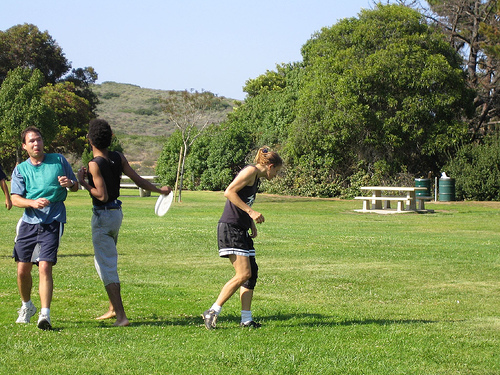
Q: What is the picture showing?
A: It is showing a field.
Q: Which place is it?
A: It is a field.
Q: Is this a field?
A: Yes, it is a field.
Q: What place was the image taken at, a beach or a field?
A: It was taken at a field.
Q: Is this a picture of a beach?
A: No, the picture is showing a field.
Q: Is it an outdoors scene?
A: Yes, it is outdoors.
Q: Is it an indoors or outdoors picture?
A: It is outdoors.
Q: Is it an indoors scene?
A: No, it is outdoors.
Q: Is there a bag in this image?
A: No, there are no bags.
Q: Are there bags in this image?
A: No, there are no bags.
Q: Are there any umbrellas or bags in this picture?
A: No, there are no bags or umbrellas.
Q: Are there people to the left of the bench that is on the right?
A: Yes, there are people to the left of the bench.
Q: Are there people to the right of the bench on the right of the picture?
A: No, the people are to the left of the bench.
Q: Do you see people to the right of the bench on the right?
A: No, the people are to the left of the bench.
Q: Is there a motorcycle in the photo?
A: No, there are no motorcycles.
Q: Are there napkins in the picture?
A: No, there are no napkins.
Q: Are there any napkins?
A: No, there are no napkins.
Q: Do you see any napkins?
A: No, there are no napkins.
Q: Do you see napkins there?
A: No, there are no napkins.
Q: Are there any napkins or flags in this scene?
A: No, there are no napkins or flags.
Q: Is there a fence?
A: No, there are no fences.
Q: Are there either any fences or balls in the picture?
A: No, there are no fences or balls.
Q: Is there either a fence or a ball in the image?
A: No, there are no fences or balls.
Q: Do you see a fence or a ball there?
A: No, there are no fences or balls.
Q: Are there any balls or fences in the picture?
A: No, there are no fences or balls.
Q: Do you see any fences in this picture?
A: No, there are no fences.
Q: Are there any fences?
A: No, there are no fences.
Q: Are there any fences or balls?
A: No, there are no fences or balls.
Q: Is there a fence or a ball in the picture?
A: No, there are no fences or balls.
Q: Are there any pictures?
A: No, there are no pictures.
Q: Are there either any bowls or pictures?
A: No, there are no pictures or bowls.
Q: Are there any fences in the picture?
A: No, there are no fences.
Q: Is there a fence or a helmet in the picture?
A: No, there are no fences or helmets.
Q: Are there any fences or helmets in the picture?
A: No, there are no fences or helmets.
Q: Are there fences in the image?
A: No, there are no fences.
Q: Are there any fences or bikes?
A: No, there are no fences or bikes.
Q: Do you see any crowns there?
A: No, there are no crowns.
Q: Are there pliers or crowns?
A: No, there are no crowns or pliers.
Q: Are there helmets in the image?
A: No, there are no helmets.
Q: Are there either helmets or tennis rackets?
A: No, there are no helmets or tennis rackets.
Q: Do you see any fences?
A: No, there are no fences.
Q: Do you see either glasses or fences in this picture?
A: No, there are no fences or glasses.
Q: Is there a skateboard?
A: No, there are no skateboards.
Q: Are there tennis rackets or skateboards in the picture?
A: No, there are no skateboards or tennis rackets.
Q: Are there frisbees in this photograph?
A: Yes, there is a frisbee.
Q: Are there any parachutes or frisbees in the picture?
A: Yes, there is a frisbee.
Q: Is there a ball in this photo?
A: No, there are no balls.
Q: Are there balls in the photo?
A: No, there are no balls.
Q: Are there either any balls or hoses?
A: No, there are no balls or hoses.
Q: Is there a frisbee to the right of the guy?
A: Yes, there is a frisbee to the right of the guy.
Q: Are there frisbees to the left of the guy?
A: No, the frisbee is to the right of the guy.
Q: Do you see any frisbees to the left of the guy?
A: No, the frisbee is to the right of the guy.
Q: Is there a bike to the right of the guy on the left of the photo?
A: No, there is a frisbee to the right of the guy.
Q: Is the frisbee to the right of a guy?
A: Yes, the frisbee is to the right of a guy.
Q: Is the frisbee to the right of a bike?
A: No, the frisbee is to the right of a guy.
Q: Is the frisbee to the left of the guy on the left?
A: No, the frisbee is to the right of the guy.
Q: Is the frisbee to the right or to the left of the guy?
A: The frisbee is to the right of the guy.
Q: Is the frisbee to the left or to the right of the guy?
A: The frisbee is to the right of the guy.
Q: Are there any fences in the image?
A: No, there are no fences.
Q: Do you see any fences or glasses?
A: No, there are no fences or glasses.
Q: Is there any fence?
A: No, there are no fences.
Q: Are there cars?
A: No, there are no cars.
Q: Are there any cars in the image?
A: No, there are no cars.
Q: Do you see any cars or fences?
A: No, there are no cars or fences.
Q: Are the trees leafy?
A: Yes, the trees are leafy.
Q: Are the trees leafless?
A: No, the trees are leafy.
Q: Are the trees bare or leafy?
A: The trees are leafy.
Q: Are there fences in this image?
A: No, there are no fences.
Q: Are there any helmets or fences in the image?
A: No, there are no fences or helmets.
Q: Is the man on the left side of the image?
A: Yes, the man is on the left of the image.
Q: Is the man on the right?
A: No, the man is on the left of the image.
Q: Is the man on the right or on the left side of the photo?
A: The man is on the left of the image.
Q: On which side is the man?
A: The man is on the left of the image.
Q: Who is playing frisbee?
A: The man is playing frisbee.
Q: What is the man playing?
A: The man is playing frisbee.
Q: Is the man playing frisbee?
A: Yes, the man is playing frisbee.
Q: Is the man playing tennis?
A: No, the man is playing frisbee.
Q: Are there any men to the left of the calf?
A: Yes, there is a man to the left of the calf.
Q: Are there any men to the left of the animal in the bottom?
A: Yes, there is a man to the left of the calf.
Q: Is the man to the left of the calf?
A: Yes, the man is to the left of the calf.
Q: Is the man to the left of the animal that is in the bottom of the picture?
A: Yes, the man is to the left of the calf.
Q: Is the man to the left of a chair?
A: No, the man is to the left of the calf.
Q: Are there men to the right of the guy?
A: Yes, there is a man to the right of the guy.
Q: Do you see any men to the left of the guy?
A: No, the man is to the right of the guy.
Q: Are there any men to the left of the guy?
A: No, the man is to the right of the guy.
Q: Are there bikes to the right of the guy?
A: No, there is a man to the right of the guy.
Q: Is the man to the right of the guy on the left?
A: Yes, the man is to the right of the guy.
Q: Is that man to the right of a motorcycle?
A: No, the man is to the right of the guy.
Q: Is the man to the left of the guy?
A: No, the man is to the right of the guy.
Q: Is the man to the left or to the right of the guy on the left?
A: The man is to the right of the guy.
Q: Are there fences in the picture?
A: No, there are no fences.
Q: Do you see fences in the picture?
A: No, there are no fences.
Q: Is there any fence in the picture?
A: No, there are no fences.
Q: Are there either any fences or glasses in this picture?
A: No, there are no fences or glasses.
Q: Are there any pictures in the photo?
A: No, there are no pictures.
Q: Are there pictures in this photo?
A: No, there are no pictures.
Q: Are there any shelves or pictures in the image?
A: No, there are no pictures or shelves.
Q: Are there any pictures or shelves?
A: No, there are no pictures or shelves.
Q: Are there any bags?
A: No, there are no bags.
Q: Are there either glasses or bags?
A: No, there are no bags or glasses.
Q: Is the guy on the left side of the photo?
A: Yes, the guy is on the left of the image.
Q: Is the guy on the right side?
A: No, the guy is on the left of the image.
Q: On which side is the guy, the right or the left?
A: The guy is on the left of the image.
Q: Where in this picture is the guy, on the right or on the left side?
A: The guy is on the left of the image.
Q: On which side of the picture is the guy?
A: The guy is on the left of the image.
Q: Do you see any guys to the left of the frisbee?
A: Yes, there is a guy to the left of the frisbee.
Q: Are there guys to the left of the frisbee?
A: Yes, there is a guy to the left of the frisbee.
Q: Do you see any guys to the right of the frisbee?
A: No, the guy is to the left of the frisbee.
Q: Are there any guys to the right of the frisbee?
A: No, the guy is to the left of the frisbee.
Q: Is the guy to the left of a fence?
A: No, the guy is to the left of the frisbee.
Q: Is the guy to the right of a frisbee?
A: No, the guy is to the left of a frisbee.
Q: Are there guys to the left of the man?
A: Yes, there is a guy to the left of the man.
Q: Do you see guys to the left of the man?
A: Yes, there is a guy to the left of the man.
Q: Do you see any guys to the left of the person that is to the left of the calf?
A: Yes, there is a guy to the left of the man.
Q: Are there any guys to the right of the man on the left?
A: No, the guy is to the left of the man.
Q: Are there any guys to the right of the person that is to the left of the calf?
A: No, the guy is to the left of the man.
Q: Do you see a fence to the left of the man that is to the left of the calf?
A: No, there is a guy to the left of the man.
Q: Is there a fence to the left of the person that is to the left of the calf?
A: No, there is a guy to the left of the man.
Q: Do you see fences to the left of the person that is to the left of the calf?
A: No, there is a guy to the left of the man.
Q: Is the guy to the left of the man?
A: Yes, the guy is to the left of the man.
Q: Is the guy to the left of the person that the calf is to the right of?
A: Yes, the guy is to the left of the man.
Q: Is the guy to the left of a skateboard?
A: No, the guy is to the left of the man.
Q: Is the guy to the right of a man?
A: No, the guy is to the left of a man.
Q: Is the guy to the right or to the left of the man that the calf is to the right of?
A: The guy is to the left of the man.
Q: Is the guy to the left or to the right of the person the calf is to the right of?
A: The guy is to the left of the man.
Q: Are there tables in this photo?
A: Yes, there is a table.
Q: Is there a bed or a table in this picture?
A: Yes, there is a table.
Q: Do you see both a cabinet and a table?
A: No, there is a table but no cabinets.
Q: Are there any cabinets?
A: No, there are no cabinets.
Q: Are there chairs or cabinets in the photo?
A: No, there are no cabinets or chairs.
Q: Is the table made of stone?
A: Yes, the table is made of stone.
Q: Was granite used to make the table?
A: No, the table is made of stone.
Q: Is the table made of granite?
A: No, the table is made of stone.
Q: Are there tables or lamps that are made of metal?
A: No, there is a table but it is made of stone.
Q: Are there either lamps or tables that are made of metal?
A: No, there is a table but it is made of stone.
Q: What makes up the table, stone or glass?
A: The table is made of stone.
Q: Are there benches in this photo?
A: Yes, there is a bench.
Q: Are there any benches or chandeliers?
A: Yes, there is a bench.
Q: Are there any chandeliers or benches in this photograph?
A: Yes, there is a bench.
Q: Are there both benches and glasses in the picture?
A: No, there is a bench but no glasses.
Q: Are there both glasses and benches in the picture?
A: No, there is a bench but no glasses.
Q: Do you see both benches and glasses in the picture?
A: No, there is a bench but no glasses.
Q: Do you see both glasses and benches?
A: No, there is a bench but no glasses.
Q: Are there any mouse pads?
A: No, there are no mouse pads.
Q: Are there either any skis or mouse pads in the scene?
A: No, there are no mouse pads or skis.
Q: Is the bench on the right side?
A: Yes, the bench is on the right of the image.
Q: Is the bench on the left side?
A: No, the bench is on the right of the image.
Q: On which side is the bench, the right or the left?
A: The bench is on the right of the image.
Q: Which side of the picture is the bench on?
A: The bench is on the right of the image.